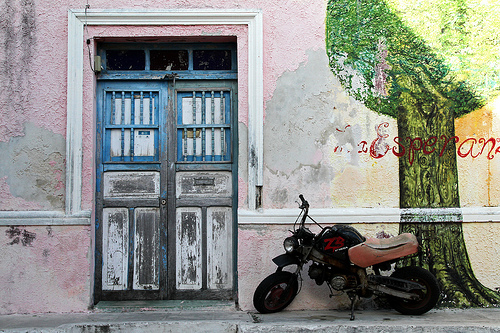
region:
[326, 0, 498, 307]
drawing of a green tree on a wall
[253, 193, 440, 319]
small black and red motorcycle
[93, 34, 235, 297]
very old wooden doors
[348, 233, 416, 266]
red seat of a motorcycle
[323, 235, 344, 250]
red logo on the tank of the motorcycle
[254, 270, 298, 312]
front wheel of a motorcycle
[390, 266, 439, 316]
rear wheel of a motorcycle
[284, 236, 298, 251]
headlight of a motorcycle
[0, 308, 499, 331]
concrete sidewalk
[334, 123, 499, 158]
Red word in another language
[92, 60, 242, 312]
the door is closed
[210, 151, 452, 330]
the motorbike is parked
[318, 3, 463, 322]
a green tree painting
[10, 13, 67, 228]
the wall is gray and pink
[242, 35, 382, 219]
the wall is gray and pink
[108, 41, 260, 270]
This is a door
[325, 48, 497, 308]
This is a mural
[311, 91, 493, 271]
This is a picture of a tree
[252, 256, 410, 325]
This is a motorcycle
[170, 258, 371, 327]
This is a wheel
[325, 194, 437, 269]
This is a seat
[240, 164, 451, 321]
The motorcycle is black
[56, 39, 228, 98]
These are windows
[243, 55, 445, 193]
The building is pink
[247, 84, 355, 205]
This is a building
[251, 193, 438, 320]
Dirt bike beside the building.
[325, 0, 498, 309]
tree painted on the building.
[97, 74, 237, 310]
doors on the building.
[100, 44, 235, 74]
Windows above the doors.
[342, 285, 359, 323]
Kick stand on the dirt bike.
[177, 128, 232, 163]
Blue rails on the door.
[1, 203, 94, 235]
White trim on the wall.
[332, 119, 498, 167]
Red writing on the wall.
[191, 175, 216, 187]
Mail slot on the door.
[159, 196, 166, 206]
lock on the door.